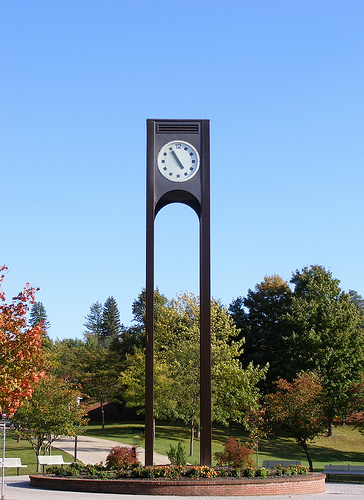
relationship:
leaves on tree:
[6, 316, 27, 369] [1, 260, 50, 421]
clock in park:
[142, 117, 212, 466] [0, 3, 362, 497]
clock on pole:
[145, 117, 210, 466] [195, 208, 214, 465]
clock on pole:
[145, 117, 210, 466] [142, 212, 156, 464]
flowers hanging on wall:
[146, 454, 202, 467] [141, 468, 286, 486]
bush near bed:
[104, 445, 142, 472] [28, 464, 328, 497]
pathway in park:
[35, 431, 193, 466] [4, 397, 362, 496]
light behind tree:
[67, 388, 90, 474] [267, 373, 333, 478]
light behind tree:
[67, 388, 90, 474] [128, 293, 268, 450]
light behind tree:
[67, 388, 90, 474] [1, 265, 49, 439]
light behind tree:
[67, 388, 90, 474] [292, 272, 361, 397]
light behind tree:
[67, 388, 90, 474] [59, 334, 136, 429]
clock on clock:
[145, 117, 210, 466] [145, 117, 210, 466]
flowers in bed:
[146, 464, 185, 478] [28, 459, 328, 496]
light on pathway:
[74, 396, 84, 463] [42, 431, 194, 466]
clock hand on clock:
[171, 150, 185, 169] [156, 140, 199, 182]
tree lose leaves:
[0, 260, 50, 421] [2, 252, 52, 421]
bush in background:
[101, 445, 144, 472] [19, 380, 361, 473]